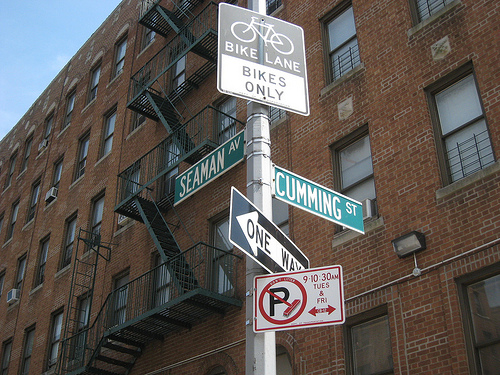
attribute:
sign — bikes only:
[219, 1, 311, 117]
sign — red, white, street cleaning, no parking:
[253, 264, 348, 333]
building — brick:
[1, 1, 499, 371]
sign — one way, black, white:
[227, 184, 310, 274]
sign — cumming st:
[274, 162, 365, 234]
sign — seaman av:
[172, 128, 246, 207]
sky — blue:
[0, 0, 123, 142]